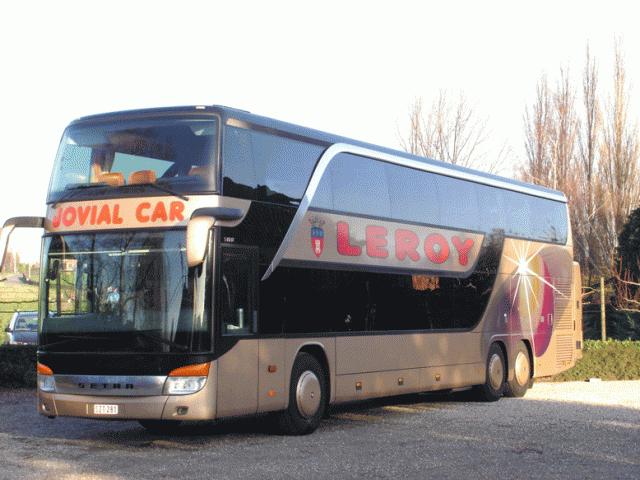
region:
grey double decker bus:
[31, 101, 590, 450]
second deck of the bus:
[53, 119, 572, 265]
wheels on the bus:
[279, 333, 535, 437]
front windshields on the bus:
[42, 118, 210, 345]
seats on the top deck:
[87, 153, 215, 187]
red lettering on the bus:
[48, 203, 472, 267]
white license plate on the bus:
[92, 404, 115, 416]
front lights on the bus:
[35, 364, 206, 396]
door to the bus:
[218, 252, 260, 416]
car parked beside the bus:
[1, 301, 47, 347]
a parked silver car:
[5, 309, 53, 344]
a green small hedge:
[0, 342, 635, 387]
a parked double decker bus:
[38, 104, 582, 434]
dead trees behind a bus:
[41, 41, 638, 433]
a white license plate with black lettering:
[92, 403, 117, 416]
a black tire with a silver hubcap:
[278, 352, 328, 437]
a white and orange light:
[164, 360, 208, 396]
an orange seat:
[128, 171, 155, 184]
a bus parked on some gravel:
[0, 104, 636, 478]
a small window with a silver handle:
[218, 243, 256, 336]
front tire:
[288, 354, 327, 430]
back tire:
[484, 343, 512, 404]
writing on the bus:
[49, 201, 180, 224]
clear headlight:
[166, 374, 214, 389]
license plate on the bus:
[90, 400, 122, 417]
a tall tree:
[531, 78, 583, 145]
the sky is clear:
[297, 49, 389, 116]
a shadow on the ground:
[383, 434, 449, 475]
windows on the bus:
[328, 279, 434, 336]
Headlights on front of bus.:
[36, 373, 208, 397]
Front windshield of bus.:
[38, 232, 209, 348]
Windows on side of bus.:
[261, 262, 479, 336]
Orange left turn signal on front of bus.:
[169, 360, 211, 377]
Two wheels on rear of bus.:
[479, 335, 538, 397]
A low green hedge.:
[572, 334, 636, 389]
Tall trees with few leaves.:
[528, 44, 636, 309]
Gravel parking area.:
[234, 380, 635, 478]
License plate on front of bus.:
[89, 404, 120, 417]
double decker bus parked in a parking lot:
[22, 90, 589, 436]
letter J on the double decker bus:
[48, 205, 63, 228]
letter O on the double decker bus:
[60, 206, 77, 226]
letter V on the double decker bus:
[74, 202, 91, 224]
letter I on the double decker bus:
[90, 202, 99, 225]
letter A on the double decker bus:
[98, 201, 113, 229]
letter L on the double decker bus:
[112, 202, 123, 224]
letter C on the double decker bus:
[132, 198, 153, 224]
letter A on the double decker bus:
[150, 197, 168, 224]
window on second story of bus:
[330, 151, 389, 219]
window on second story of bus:
[383, 158, 441, 224]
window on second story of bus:
[431, 171, 481, 231]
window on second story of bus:
[475, 181, 507, 234]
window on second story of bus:
[529, 195, 568, 244]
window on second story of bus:
[45, 116, 218, 203]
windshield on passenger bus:
[39, 227, 213, 357]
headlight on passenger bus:
[34, 372, 59, 395]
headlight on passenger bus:
[160, 375, 207, 396]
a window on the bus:
[241, 114, 266, 185]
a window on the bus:
[270, 125, 304, 198]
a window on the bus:
[336, 154, 359, 207]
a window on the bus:
[385, 151, 412, 225]